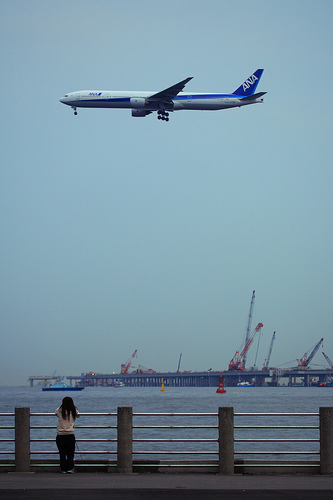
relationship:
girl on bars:
[58, 397, 78, 476] [0, 412, 332, 464]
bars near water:
[0, 412, 332, 464] [4, 388, 331, 459]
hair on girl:
[62, 395, 76, 421] [58, 397, 78, 476]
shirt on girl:
[56, 410, 77, 433] [58, 397, 78, 476]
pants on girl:
[58, 433, 78, 471] [58, 397, 78, 476]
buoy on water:
[213, 369, 228, 394] [4, 388, 331, 459]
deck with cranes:
[35, 375, 328, 387] [124, 290, 325, 372]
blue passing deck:
[42, 376, 85, 391] [35, 375, 328, 387]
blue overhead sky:
[8, 8, 326, 361] [6, 6, 324, 366]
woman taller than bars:
[58, 397, 78, 476] [0, 412, 332, 464]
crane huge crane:
[228, 323, 264, 371] [228, 324, 264, 371]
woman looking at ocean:
[58, 397, 78, 476] [4, 388, 331, 459]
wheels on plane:
[156, 108, 171, 124] [60, 68, 275, 123]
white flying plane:
[60, 88, 264, 113] [60, 68, 275, 123]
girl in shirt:
[58, 397, 78, 476] [56, 410, 77, 433]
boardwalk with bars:
[4, 473, 329, 500] [0, 412, 332, 464]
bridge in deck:
[35, 375, 328, 387] [30, 371, 328, 387]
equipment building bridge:
[124, 290, 325, 372] [35, 375, 328, 387]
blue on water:
[42, 376, 85, 391] [4, 388, 331, 459]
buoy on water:
[158, 377, 171, 393] [4, 388, 331, 459]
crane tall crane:
[121, 350, 138, 375] [118, 347, 143, 373]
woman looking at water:
[58, 397, 78, 476] [4, 388, 331, 459]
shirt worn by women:
[56, 410, 77, 433] [58, 397, 78, 476]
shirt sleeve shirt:
[55, 405, 81, 435] [56, 410, 77, 433]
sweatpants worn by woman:
[58, 433, 78, 471] [58, 397, 78, 476]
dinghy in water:
[213, 369, 228, 394] [4, 388, 331, 459]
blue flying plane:
[83, 69, 275, 107] [60, 68, 275, 123]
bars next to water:
[3, 412, 332, 469] [4, 388, 331, 459]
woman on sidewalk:
[58, 397, 78, 476] [4, 473, 329, 500]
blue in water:
[42, 376, 85, 391] [4, 388, 331, 459]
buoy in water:
[213, 369, 228, 394] [4, 388, 331, 459]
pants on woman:
[58, 433, 78, 471] [58, 397, 78, 476]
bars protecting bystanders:
[0, 412, 332, 464] [58, 397, 78, 476]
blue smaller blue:
[40, 384, 83, 392] [42, 376, 85, 391]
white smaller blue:
[56, 377, 68, 389] [42, 376, 85, 391]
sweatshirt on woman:
[56, 410, 77, 433] [58, 397, 78, 476]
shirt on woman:
[55, 405, 81, 435] [58, 397, 78, 476]